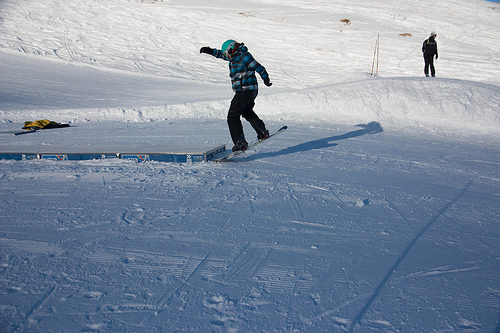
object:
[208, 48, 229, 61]
arm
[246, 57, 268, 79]
arm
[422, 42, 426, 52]
arm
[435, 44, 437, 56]
arm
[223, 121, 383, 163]
shadow cast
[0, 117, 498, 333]
ground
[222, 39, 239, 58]
helmet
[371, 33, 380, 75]
psticks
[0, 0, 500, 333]
snow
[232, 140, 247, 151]
shoe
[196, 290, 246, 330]
prints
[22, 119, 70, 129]
coat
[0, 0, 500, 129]
hill side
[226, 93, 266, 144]
pants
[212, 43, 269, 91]
coat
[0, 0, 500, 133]
hill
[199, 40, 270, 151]
man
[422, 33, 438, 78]
man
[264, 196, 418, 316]
white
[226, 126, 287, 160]
board